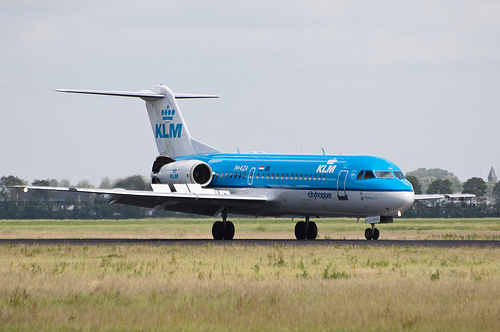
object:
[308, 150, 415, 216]
front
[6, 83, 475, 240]
plane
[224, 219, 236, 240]
wheel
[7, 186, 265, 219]
wing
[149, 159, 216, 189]
engine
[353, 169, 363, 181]
window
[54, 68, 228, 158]
tail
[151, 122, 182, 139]
klm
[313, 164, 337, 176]
klm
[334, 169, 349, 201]
door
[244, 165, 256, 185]
door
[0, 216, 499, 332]
ground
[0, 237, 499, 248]
runway